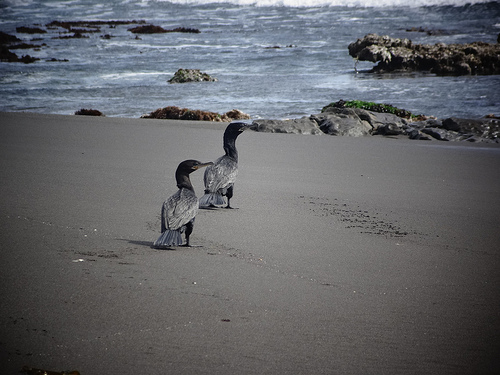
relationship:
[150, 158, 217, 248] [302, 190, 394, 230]
bird walking across sand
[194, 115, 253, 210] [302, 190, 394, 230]
bird walking across sand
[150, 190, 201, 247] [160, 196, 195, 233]
back covered in dark feathers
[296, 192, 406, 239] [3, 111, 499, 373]
marks left in sand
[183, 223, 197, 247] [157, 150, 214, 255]
leg of bird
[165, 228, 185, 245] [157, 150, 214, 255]
leg of bird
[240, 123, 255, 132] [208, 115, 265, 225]
beak of bird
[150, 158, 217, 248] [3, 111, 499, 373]
bird standing on sand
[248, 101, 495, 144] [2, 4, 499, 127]
rock in water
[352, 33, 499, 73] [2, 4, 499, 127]
rock in water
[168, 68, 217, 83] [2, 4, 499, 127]
rock in water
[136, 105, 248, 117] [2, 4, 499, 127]
rock in water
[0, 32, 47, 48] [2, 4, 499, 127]
rock in water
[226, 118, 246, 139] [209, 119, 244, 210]
head of bird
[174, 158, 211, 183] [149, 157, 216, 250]
head of bird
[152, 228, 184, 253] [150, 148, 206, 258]
tail feathers of bird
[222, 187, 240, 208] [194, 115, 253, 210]
leg of bird